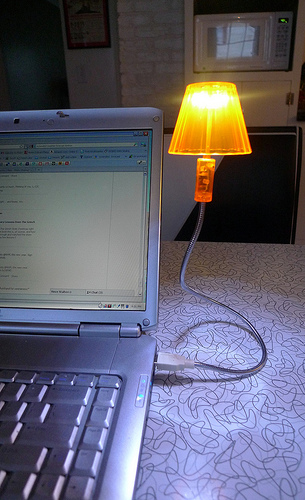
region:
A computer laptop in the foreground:
[0, 94, 169, 496]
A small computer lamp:
[159, 69, 285, 213]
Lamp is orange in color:
[153, 74, 288, 383]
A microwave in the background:
[190, 6, 292, 70]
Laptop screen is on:
[1, 125, 150, 310]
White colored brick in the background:
[113, 0, 182, 124]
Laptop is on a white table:
[126, 228, 302, 497]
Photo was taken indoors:
[0, 0, 296, 496]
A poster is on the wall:
[58, 0, 110, 55]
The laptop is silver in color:
[1, 100, 177, 498]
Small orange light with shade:
[167, 80, 251, 201]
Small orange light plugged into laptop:
[156, 82, 267, 376]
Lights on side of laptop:
[134, 369, 148, 407]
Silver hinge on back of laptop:
[74, 322, 144, 338]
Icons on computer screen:
[1, 159, 69, 167]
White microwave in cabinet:
[193, 10, 294, 73]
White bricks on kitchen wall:
[114, 1, 185, 128]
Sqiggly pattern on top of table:
[136, 240, 302, 497]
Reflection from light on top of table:
[152, 343, 263, 498]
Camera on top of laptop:
[12, 116, 19, 124]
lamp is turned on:
[169, 69, 250, 212]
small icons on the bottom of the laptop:
[102, 303, 128, 308]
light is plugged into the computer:
[155, 78, 287, 386]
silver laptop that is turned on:
[0, 103, 166, 498]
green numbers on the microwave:
[279, 19, 288, 22]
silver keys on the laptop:
[0, 368, 108, 499]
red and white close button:
[143, 129, 148, 136]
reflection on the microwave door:
[205, 20, 261, 56]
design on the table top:
[132, 238, 304, 497]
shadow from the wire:
[164, 311, 257, 356]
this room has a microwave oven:
[190, 4, 296, 77]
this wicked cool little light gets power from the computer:
[156, 78, 272, 383]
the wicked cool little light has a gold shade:
[168, 79, 251, 158]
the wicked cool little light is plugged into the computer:
[154, 79, 269, 405]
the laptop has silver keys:
[0, 361, 121, 498]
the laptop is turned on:
[0, 103, 161, 328]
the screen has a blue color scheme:
[1, 125, 154, 311]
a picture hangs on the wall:
[61, 0, 115, 50]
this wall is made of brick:
[115, 0, 186, 127]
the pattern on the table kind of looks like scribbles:
[143, 238, 303, 498]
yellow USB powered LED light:
[152, 77, 270, 380]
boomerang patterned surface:
[133, 234, 302, 498]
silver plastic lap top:
[0, 106, 167, 499]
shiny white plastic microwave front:
[190, 9, 293, 74]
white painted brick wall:
[115, 1, 186, 129]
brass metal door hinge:
[285, 90, 295, 104]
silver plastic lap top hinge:
[74, 317, 122, 341]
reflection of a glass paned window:
[208, 20, 255, 60]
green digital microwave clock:
[277, 14, 290, 22]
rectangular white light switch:
[73, 62, 88, 85]